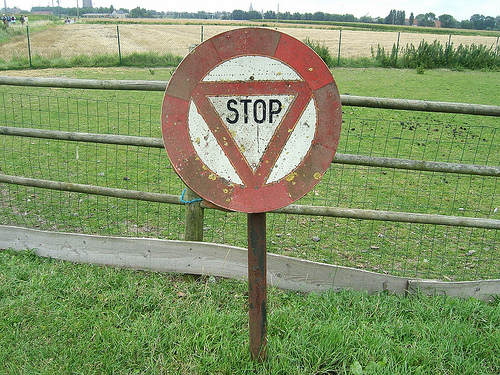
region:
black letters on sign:
[219, 93, 286, 125]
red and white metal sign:
[157, 26, 340, 218]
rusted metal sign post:
[241, 219, 277, 359]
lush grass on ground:
[36, 285, 181, 365]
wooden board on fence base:
[51, 237, 182, 265]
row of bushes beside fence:
[380, 33, 495, 70]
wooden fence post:
[184, 205, 203, 242]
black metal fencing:
[364, 223, 456, 265]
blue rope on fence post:
[171, 188, 194, 213]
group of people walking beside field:
[0, 11, 35, 27]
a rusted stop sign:
[143, 40, 373, 219]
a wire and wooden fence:
[1, 91, 469, 256]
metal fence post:
[0, 17, 150, 69]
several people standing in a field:
[1, 7, 36, 36]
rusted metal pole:
[216, 213, 292, 372]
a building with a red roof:
[400, 13, 457, 31]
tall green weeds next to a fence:
[363, 42, 489, 73]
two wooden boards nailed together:
[345, 270, 484, 307]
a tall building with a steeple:
[234, 0, 270, 16]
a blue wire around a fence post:
[172, 189, 202, 209]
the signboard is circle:
[136, 12, 464, 300]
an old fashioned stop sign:
[154, 28, 383, 235]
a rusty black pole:
[235, 220, 266, 357]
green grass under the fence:
[18, 261, 157, 371]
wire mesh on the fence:
[356, 171, 469, 208]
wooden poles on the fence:
[35, 84, 145, 227]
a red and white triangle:
[193, 67, 318, 178]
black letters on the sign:
[223, 97, 290, 124]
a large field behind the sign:
[96, 17, 449, 49]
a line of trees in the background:
[280, 10, 368, 22]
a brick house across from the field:
[81, 9, 138, 17]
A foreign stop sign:
[100, 20, 445, 362]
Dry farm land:
[11, 0, 176, 70]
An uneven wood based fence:
[10, 210, 490, 300]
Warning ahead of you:
[147, 16, 384, 232]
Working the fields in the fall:
[0, 0, 150, 90]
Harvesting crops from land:
[0, 0, 151, 42]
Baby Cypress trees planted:
[365, 0, 496, 85]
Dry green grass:
[0, 281, 206, 371]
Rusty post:
[230, 202, 300, 362]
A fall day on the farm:
[0, 0, 498, 345]